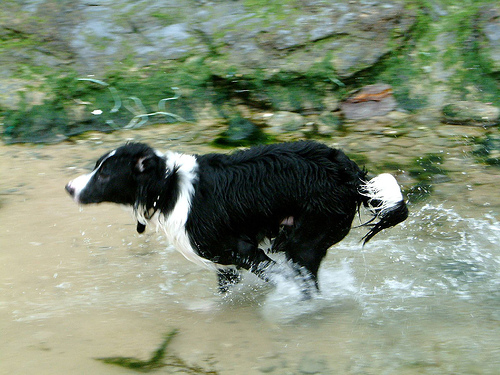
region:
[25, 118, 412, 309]
black and white dog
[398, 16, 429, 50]
green grass on gray rocks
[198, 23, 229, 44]
green grass on gray rocks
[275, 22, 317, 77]
green grass on gray rocks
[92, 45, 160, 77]
green grass on gray rocks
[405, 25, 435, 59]
green grass on gray rocks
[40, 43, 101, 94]
green grass on gray rocks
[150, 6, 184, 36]
green grass on gray rocks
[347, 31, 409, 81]
green grass on gray rocks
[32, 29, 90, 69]
green moss on gray rock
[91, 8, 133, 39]
green moss on gray rock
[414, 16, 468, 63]
green moss on gray rock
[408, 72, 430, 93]
green moss on gray rock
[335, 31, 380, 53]
green moss on gray rock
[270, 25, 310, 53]
green moss on gray rock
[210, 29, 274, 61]
green moss on gray rock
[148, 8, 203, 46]
green moss on gray rock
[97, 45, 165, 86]
green moss on gray rock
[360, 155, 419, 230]
tail of the dog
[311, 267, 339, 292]
leg of the dog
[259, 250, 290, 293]
leg of the dog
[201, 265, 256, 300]
leg of the dog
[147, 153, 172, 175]
ear of the dog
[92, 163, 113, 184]
eye of the dog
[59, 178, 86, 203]
nose of the dog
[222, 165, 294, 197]
the dog is black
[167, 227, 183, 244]
the dog is white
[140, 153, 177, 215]
neck of the dog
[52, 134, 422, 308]
Dog on the water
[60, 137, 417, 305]
Dog is on the water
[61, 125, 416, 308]
Black and white dog on the water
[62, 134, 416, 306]
Black and white dog is on the water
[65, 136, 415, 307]
Dog running in the water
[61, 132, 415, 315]
Dog is running in the water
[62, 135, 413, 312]
Black and white dog running in the water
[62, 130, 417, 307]
Black and white dog is running in the water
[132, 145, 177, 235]
Dog wearing a collar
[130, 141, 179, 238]
Dog is wearing a collar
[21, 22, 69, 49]
green moss on gray rocks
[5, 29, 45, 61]
green moss on gray rocks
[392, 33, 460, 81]
green moss on gray rocks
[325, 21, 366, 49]
green moss on gray rocks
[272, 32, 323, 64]
green moss on gray rocks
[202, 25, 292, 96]
green moss on gray rocks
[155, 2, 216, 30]
green moss on gray rocks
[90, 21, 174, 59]
green moss on gray rocks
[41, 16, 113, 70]
green moss on gray rocks